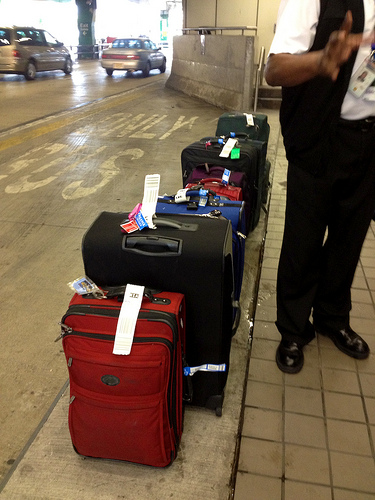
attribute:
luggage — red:
[187, 177, 239, 197]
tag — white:
[115, 283, 137, 354]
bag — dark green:
[214, 112, 269, 142]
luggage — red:
[43, 200, 296, 470]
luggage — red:
[53, 278, 192, 471]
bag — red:
[23, 194, 228, 431]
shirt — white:
[266, 0, 374, 122]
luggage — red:
[185, 170, 247, 203]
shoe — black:
[314, 318, 373, 362]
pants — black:
[272, 141, 373, 328]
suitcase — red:
[53, 285, 189, 473]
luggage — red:
[53, 108, 273, 470]